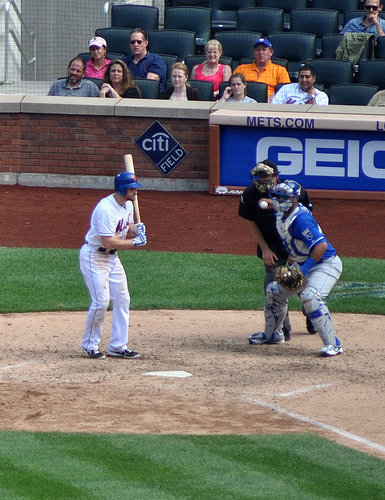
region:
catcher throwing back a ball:
[52, 106, 359, 394]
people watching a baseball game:
[50, 24, 342, 173]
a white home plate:
[116, 330, 248, 415]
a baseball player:
[81, 141, 186, 374]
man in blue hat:
[234, 28, 295, 115]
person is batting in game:
[74, 151, 147, 362]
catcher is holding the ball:
[237, 180, 342, 355]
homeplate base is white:
[141, 366, 192, 377]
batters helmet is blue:
[114, 170, 142, 198]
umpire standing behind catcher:
[235, 159, 321, 339]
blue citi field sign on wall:
[136, 120, 189, 175]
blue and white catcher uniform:
[248, 177, 342, 355]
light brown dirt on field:
[0, 304, 383, 463]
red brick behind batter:
[1, 112, 208, 179]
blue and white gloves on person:
[132, 220, 147, 247]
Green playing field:
[134, 446, 220, 488]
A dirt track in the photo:
[151, 350, 270, 420]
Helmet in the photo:
[265, 172, 299, 195]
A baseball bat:
[125, 151, 148, 222]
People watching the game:
[64, 33, 269, 110]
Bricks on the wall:
[45, 126, 97, 161]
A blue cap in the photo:
[249, 32, 272, 47]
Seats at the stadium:
[202, 10, 304, 45]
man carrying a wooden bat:
[78, 152, 146, 357]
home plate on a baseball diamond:
[139, 368, 192, 380]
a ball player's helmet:
[115, 172, 141, 195]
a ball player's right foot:
[82, 345, 106, 360]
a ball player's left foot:
[109, 347, 138, 359]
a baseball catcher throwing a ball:
[249, 181, 344, 354]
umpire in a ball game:
[236, 161, 310, 343]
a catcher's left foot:
[318, 342, 343, 355]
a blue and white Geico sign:
[219, 123, 383, 192]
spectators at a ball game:
[52, 3, 384, 102]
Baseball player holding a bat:
[78, 153, 147, 359]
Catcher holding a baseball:
[248, 178, 344, 356]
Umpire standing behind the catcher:
[240, 160, 317, 339]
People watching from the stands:
[50, 0, 383, 106]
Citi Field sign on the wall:
[136, 120, 187, 175]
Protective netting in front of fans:
[0, 0, 383, 106]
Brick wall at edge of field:
[0, 116, 211, 185]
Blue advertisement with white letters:
[219, 130, 380, 189]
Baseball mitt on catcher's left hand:
[273, 263, 305, 292]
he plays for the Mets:
[91, 153, 153, 268]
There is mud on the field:
[105, 374, 238, 419]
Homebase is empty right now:
[138, 363, 222, 393]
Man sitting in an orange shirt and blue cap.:
[231, 38, 293, 104]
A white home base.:
[142, 369, 192, 378]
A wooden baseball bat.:
[123, 153, 141, 223]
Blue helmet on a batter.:
[113, 170, 141, 195]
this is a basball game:
[21, 41, 321, 374]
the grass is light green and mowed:
[78, 442, 217, 493]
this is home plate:
[133, 341, 231, 423]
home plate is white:
[129, 344, 200, 401]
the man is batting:
[73, 151, 164, 342]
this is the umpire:
[212, 163, 304, 303]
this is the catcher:
[263, 182, 329, 291]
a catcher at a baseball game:
[259, 178, 354, 351]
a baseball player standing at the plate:
[65, 146, 203, 391]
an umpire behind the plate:
[243, 145, 311, 240]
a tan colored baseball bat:
[116, 141, 157, 236]